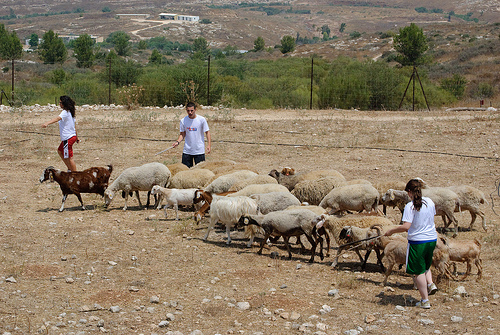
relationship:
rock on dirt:
[236, 299, 251, 310] [0, 108, 499, 335]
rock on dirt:
[279, 310, 287, 318] [0, 108, 499, 335]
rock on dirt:
[290, 310, 300, 319] [0, 108, 499, 335]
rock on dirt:
[314, 321, 328, 331] [0, 108, 499, 335]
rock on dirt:
[318, 303, 332, 312] [0, 108, 499, 335]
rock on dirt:
[320, 303, 331, 312] [0, 108, 499, 335]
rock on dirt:
[325, 288, 339, 298] [0, 108, 499, 335]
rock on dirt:
[421, 316, 434, 326] [0, 108, 499, 335]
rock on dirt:
[4, 275, 16, 285] [0, 108, 499, 335]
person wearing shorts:
[41, 95, 80, 173] [56, 133, 76, 156]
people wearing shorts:
[382, 179, 439, 309] [405, 236, 438, 275]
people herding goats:
[382, 179, 439, 309] [134, 127, 487, 229]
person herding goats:
[172, 103, 212, 167] [134, 127, 487, 229]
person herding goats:
[43, 94, 79, 168] [134, 127, 487, 229]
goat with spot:
[36, 159, 113, 211] [68, 177, 73, 183]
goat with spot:
[36, 159, 113, 211] [75, 179, 79, 184]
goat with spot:
[36, 159, 113, 211] [88, 180, 94, 187]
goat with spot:
[36, 159, 113, 211] [91, 170, 97, 178]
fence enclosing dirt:
[2, 53, 499, 110] [0, 108, 499, 335]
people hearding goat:
[36, 90, 488, 310] [33, 158, 113, 203]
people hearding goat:
[36, 90, 488, 310] [166, 168, 215, 189]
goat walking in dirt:
[33, 162, 115, 215] [25, 196, 285, 333]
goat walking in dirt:
[151, 185, 206, 222] [1, 108, 497, 333]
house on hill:
[156, 9, 202, 27] [86, 3, 297, 56]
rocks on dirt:
[0, 256, 490, 333] [0, 108, 499, 335]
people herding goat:
[382, 179, 439, 309] [151, 185, 206, 222]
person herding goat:
[41, 95, 80, 173] [151, 185, 206, 222]